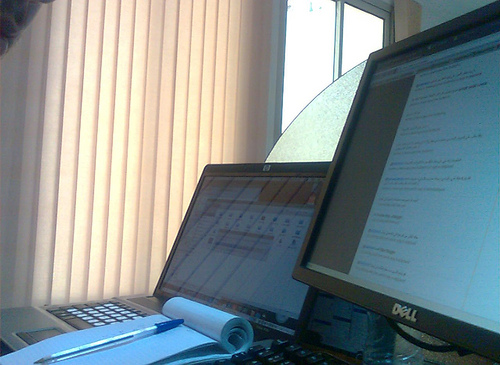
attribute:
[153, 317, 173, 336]
cap — blue 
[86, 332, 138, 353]
pen — blue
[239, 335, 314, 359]
keyboard — external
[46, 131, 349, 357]
laptop — open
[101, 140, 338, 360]
laptop — open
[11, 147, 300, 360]
laptop — gray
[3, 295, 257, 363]
pages — white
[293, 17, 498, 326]
computer monitor — on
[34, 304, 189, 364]
pen — blue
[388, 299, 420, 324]
words — written, grey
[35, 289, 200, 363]
pen — blue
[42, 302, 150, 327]
keyboard — white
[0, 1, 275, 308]
blinds — open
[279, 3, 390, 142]
window — bright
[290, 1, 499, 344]
computer — open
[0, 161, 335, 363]
laptop — open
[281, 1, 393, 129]
window — closed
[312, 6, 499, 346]
monitor — black 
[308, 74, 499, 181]
computer — on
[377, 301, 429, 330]
dell — gray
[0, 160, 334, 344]
laptop — open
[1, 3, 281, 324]
wall — white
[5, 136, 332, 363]
laptop — open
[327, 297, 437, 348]
bottle — plastic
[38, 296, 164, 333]
keyboard — gray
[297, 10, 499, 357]
monitor — dell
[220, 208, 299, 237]
words — blue, written